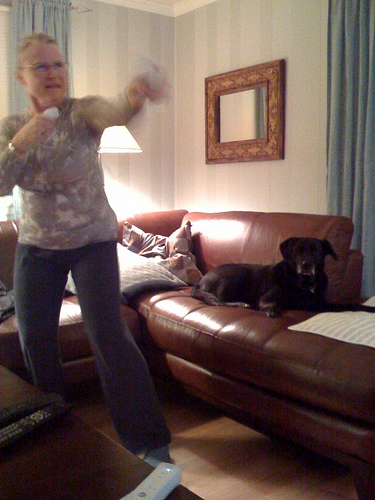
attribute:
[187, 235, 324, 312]
dog — black 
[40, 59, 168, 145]
controls — two black remote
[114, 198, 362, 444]
couch — brown sectional 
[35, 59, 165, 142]
game — video 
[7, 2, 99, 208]
curtains — blue 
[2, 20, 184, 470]
woman — older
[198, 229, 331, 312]
dog — black 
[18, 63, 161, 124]
remotes — game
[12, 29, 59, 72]
hair — blonde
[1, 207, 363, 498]
couch — brown, large, leather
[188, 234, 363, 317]
dog — black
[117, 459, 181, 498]
game controller — white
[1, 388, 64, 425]
remote — black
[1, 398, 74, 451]
remote — black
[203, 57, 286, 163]
mirror — framed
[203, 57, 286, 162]
wall mirror — brown, framed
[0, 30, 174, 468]
lady — older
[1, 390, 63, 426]
remote control — black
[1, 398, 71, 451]
remote control — black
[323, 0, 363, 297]
curtain — blue, long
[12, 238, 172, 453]
pants — dark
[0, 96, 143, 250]
shirt — floral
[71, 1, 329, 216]
wallpaper — light blue, striped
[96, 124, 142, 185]
lamp — lit up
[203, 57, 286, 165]
frame — decorative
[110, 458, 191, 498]
controller — white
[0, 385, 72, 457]
remotes — black, television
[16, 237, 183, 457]
pants — dark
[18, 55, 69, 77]
glasses — thin, metal framed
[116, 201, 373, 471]
couch — leather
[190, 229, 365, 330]
dog — large, black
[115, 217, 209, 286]
pillow — brown, white, checkered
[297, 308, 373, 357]
towel — white, striped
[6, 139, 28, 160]
watch — shiny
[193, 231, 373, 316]
dog — large, black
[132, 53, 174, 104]
controller — Wii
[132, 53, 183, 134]
controller — white